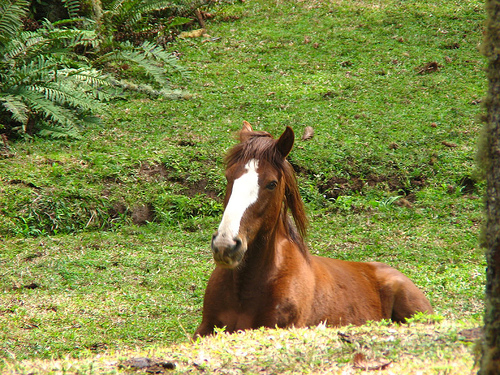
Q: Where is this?
A: This is at the field.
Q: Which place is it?
A: It is a field.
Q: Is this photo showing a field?
A: Yes, it is showing a field.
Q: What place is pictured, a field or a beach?
A: It is a field.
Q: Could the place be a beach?
A: No, it is a field.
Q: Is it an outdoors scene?
A: Yes, it is outdoors.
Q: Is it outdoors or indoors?
A: It is outdoors.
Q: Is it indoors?
A: No, it is outdoors.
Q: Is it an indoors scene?
A: No, it is outdoors.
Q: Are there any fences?
A: No, there are no fences.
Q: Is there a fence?
A: No, there are no fences.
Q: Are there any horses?
A: Yes, there is a horse.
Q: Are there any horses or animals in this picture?
A: Yes, there is a horse.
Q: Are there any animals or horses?
A: Yes, there is a horse.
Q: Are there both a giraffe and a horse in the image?
A: No, there is a horse but no giraffes.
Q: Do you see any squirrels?
A: No, there are no squirrels.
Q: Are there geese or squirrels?
A: No, there are no squirrels or geese.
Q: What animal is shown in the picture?
A: The animal is a horse.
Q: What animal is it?
A: The animal is a horse.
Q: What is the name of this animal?
A: This is a horse.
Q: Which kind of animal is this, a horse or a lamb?
A: This is a horse.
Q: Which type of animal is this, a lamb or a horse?
A: This is a horse.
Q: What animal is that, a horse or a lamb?
A: That is a horse.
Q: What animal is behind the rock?
A: The animal is a horse.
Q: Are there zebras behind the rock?
A: No, there is a horse behind the rock.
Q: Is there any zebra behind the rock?
A: No, there is a horse behind the rock.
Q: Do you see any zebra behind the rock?
A: No, there is a horse behind the rock.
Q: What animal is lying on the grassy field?
A: The horse is lying on the field.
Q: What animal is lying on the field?
A: The horse is lying on the field.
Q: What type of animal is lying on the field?
A: The animal is a horse.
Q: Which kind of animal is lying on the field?
A: The animal is a horse.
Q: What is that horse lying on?
A: The horse is lying on the field.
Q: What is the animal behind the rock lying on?
A: The horse is lying on the field.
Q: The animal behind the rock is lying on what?
A: The horse is lying on the field.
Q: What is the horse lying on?
A: The horse is lying on the field.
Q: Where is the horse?
A: The horse is in the grass.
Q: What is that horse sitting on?
A: The horse is sitting on the grass.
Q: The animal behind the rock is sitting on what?
A: The horse is sitting on the grass.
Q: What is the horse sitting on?
A: The horse is sitting on the grass.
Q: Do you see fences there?
A: No, there are no fences.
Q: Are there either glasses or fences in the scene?
A: No, there are no fences or glasses.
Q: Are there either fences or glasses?
A: No, there are no fences or glasses.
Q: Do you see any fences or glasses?
A: No, there are no fences or glasses.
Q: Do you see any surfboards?
A: No, there are no surfboards.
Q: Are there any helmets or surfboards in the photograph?
A: No, there are no surfboards or helmets.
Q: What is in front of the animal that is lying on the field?
A: The rock is in front of the horse.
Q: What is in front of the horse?
A: The rock is in front of the horse.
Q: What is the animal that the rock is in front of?
A: The animal is a horse.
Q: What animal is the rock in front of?
A: The rock is in front of the horse.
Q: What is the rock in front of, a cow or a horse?
A: The rock is in front of a horse.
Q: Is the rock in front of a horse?
A: Yes, the rock is in front of a horse.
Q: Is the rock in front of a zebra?
A: No, the rock is in front of a horse.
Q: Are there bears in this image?
A: No, there are no bears.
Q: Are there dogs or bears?
A: No, there are no bears or dogs.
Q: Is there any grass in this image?
A: Yes, there is grass.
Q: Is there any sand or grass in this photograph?
A: Yes, there is grass.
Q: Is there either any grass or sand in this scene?
A: Yes, there is grass.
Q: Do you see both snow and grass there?
A: No, there is grass but no snow.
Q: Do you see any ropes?
A: No, there are no ropes.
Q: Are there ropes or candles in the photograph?
A: No, there are no ropes or candles.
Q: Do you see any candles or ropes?
A: No, there are no ropes or candles.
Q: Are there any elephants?
A: No, there are no elephants.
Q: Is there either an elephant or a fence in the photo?
A: No, there are no elephants or fences.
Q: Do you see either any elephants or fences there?
A: No, there are no fences or elephants.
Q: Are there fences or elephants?
A: No, there are no fences or elephants.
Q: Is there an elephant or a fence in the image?
A: No, there are no fences or elephants.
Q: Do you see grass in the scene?
A: Yes, there is grass.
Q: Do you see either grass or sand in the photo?
A: Yes, there is grass.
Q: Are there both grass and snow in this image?
A: No, there is grass but no snow.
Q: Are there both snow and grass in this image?
A: No, there is grass but no snow.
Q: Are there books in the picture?
A: No, there are no books.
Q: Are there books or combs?
A: No, there are no books or combs.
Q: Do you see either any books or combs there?
A: No, there are no books or combs.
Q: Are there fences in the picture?
A: No, there are no fences.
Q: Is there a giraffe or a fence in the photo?
A: No, there are no fences or giraffes.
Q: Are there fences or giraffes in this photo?
A: No, there are no fences or giraffes.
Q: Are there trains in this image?
A: No, there are no trains.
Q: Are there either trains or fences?
A: No, there are no trains or fences.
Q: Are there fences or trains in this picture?
A: No, there are no trains or fences.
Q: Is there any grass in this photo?
A: Yes, there is grass.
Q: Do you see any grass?
A: Yes, there is grass.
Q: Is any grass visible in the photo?
A: Yes, there is grass.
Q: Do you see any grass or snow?
A: Yes, there is grass.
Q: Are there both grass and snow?
A: No, there is grass but no snow.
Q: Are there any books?
A: No, there are no books.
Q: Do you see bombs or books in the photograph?
A: No, there are no books or bombs.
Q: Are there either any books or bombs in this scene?
A: No, there are no books or bombs.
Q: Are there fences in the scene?
A: No, there are no fences.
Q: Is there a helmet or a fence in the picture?
A: No, there are no fences or helmets.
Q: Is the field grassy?
A: Yes, the field is grassy.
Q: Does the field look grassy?
A: Yes, the field is grassy.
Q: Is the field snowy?
A: No, the field is grassy.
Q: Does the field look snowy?
A: No, the field is grassy.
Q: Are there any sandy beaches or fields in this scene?
A: No, there is a field but it is grassy.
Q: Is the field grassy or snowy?
A: The field is grassy.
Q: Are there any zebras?
A: No, there are no zebras.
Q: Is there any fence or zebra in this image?
A: No, there are no zebras or fences.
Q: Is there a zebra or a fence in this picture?
A: No, there are no zebras or fences.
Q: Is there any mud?
A: Yes, there is mud.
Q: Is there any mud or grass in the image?
A: Yes, there is mud.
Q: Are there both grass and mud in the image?
A: Yes, there are both mud and grass.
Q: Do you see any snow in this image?
A: No, there is no snow.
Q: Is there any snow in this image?
A: No, there is no snow.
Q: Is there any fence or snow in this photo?
A: No, there are no snow or fences.